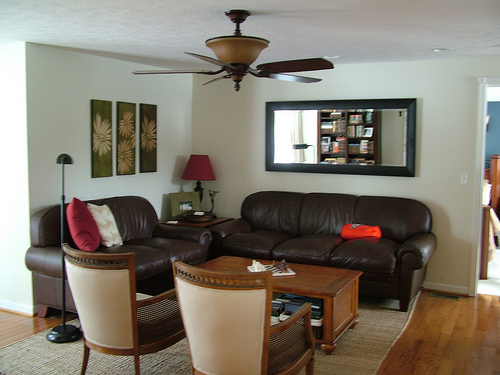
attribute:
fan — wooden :
[122, 14, 353, 122]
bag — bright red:
[338, 221, 381, 238]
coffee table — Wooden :
[190, 248, 365, 358]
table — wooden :
[161, 228, 380, 368]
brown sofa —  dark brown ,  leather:
[209, 188, 437, 312]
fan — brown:
[111, 13, 386, 128]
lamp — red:
[165, 144, 298, 235]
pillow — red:
[59, 199, 101, 251]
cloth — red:
[338, 219, 383, 240]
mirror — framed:
[265, 97, 417, 179]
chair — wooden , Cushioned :
[168, 261, 318, 373]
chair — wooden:
[181, 238, 308, 370]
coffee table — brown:
[153, 219, 404, 349]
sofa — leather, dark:
[220, 186, 445, 282]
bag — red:
[335, 208, 381, 248]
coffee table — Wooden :
[183, 247, 368, 347]